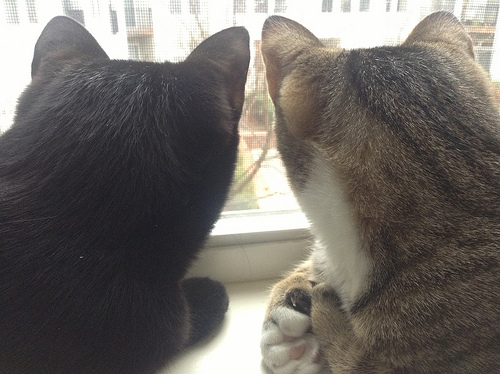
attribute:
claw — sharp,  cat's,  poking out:
[261, 323, 311, 365]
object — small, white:
[73, 251, 86, 263]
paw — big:
[258, 269, 332, 371]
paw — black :
[236, 279, 366, 371]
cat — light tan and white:
[251, 22, 496, 298]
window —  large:
[1, 0, 495, 215]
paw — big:
[239, 279, 324, 349]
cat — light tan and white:
[238, 44, 475, 319]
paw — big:
[255, 274, 327, 372]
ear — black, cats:
[177, 24, 289, 123]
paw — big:
[258, 272, 313, 372]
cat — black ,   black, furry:
[0, 24, 261, 371]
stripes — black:
[335, 40, 498, 226]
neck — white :
[301, 187, 499, 257]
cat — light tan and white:
[256, 21, 499, 352]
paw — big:
[244, 265, 352, 370]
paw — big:
[260, 290, 325, 372]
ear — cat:
[256, 19, 340, 91]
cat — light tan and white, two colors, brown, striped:
[256, 7, 493, 372]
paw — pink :
[244, 252, 348, 372]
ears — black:
[21, 1, 259, 111]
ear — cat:
[402, 11, 475, 55]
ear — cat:
[187, 25, 251, 113]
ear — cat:
[32, 14, 106, 62]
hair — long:
[263, 15, 293, 44]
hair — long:
[433, 13, 465, 41]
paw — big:
[250, 256, 344, 371]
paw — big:
[250, 261, 338, 371]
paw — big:
[251, 266, 331, 371]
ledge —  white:
[204, 211, 317, 280]